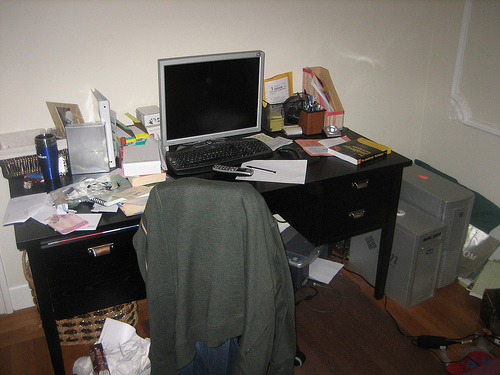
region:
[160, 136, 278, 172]
Black keyboard in front of monitor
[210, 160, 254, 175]
Gray telephone in front of black keyboard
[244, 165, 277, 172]
Pencil next to telephone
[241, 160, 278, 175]
Pencil on top of white paper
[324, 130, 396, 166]
Book on top of wooden desk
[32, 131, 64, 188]
Blue thermo cup on top of wooden desk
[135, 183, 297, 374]
Large gray jacket in front of desk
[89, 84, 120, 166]
White binder against wall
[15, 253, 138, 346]
Brown basket under wooden desk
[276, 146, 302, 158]
Black mouse next to black keyboard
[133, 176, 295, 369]
A jacket on the back of a chair.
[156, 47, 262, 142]
The monitor's screen is black.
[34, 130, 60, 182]
A small traveller's mug.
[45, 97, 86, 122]
A picture in a brown frame.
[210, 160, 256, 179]
A telephone on the desk.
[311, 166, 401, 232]
Two small drawers with metal handles.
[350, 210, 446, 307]
A computer on the floor.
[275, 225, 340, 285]
A printer under the desk.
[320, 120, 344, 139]
The base for the cordless phone.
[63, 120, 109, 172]
A thin silver box.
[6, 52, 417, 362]
Computer on a messy desk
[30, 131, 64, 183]
blue cup on the desk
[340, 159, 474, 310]
computer hardware on the floor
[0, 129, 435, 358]
the desk is black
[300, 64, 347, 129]
magazine holder on desk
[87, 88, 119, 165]
notebook on desk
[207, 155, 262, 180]
the phone is on the desk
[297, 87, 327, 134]
pens in a container on the desk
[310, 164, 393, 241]
two drawers in desk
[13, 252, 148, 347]
a basket under the desk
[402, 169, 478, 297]
tall silver tower on the floor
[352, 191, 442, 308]
short tower in the floor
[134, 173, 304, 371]
gray jacket on the chair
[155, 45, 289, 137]
silver monitor on desk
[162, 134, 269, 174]
black keyboard on desk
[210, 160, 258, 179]
silver cordless phone on desk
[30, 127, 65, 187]
blue cup with silver top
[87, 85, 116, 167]
white binder on desk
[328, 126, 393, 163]
book laying on desk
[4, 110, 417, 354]
black desk cluttered with papers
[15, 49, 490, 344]
dirty office with desktop computer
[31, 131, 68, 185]
blue shinny coffee mug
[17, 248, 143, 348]
brown basket underneath desk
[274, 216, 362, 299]
gray printer with white paper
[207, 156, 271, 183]
black and silver phone laying on a desk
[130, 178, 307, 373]
chair with gray coat hanging on it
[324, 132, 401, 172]
yellow and black book laying on a desk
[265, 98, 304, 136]
yellow sticky notes inside a storage compartment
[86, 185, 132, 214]
a notebook on the bottom of paper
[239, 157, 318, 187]
black pen on top of white paper